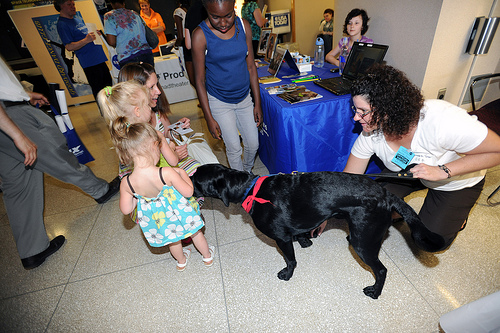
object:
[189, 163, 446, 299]
dog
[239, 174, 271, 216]
tie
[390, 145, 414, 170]
tag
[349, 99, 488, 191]
shirt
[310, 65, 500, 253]
woman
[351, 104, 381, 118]
glasses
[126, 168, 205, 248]
dress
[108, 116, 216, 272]
girl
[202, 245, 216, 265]
sandals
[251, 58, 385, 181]
cloth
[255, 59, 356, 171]
table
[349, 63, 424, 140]
hair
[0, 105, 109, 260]
pants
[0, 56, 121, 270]
man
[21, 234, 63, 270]
shoes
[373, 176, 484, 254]
pants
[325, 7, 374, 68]
woman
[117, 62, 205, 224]
woman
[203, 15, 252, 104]
tank top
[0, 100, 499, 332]
floor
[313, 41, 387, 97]
laptop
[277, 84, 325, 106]
magazine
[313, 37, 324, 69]
water bottle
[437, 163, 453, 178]
bracelet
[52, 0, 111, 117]
man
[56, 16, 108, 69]
shirt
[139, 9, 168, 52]
shirt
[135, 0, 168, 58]
woman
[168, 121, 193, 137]
card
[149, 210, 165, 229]
flowers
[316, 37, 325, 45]
top